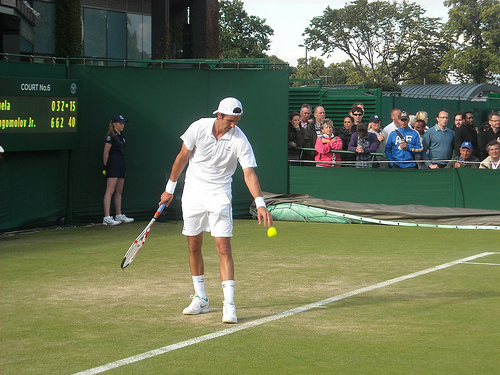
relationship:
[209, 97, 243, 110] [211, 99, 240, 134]
hat on h head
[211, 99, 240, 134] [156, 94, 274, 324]
head of tennis player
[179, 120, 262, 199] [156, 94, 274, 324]
shirt on a tennis player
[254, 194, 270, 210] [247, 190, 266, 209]
band on h wrist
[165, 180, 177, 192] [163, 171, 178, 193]
band on h wrist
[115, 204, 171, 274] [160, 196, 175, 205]
tennis racket in h hand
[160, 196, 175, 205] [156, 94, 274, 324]
hand of tennis player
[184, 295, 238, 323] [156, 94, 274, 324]
shoes on tennis player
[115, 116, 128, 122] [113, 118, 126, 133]
hat on her head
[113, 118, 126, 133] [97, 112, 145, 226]
head of woman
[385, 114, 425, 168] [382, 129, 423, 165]
spectators wearing jacket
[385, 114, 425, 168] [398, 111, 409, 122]
spectators wearing hat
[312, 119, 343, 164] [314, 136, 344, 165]
lady wearing coat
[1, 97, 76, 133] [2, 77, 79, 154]
text on display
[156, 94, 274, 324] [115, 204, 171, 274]
tennis player holding tennis racket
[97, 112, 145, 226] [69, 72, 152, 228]
woman standing in corner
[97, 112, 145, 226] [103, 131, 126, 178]
woman wearing black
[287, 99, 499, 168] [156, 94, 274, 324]
spectators watching tennis player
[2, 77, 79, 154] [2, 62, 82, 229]
display on wall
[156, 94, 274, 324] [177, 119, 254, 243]
tennis player wearing white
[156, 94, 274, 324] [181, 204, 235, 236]
tennis player wearing shorts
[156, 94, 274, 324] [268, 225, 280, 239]
tennis player serving tennis ball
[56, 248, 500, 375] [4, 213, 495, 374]
markings on tennis court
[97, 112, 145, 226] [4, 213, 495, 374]
woman on tennis court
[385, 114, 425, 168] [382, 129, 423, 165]
spectators in jacket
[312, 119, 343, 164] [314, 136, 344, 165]
lady in coat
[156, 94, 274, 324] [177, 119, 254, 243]
tennis player wearing all white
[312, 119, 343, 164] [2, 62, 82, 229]
lady standing near wall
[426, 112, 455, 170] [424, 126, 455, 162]
guy wearing sweater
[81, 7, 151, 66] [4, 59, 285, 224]
doors above wall